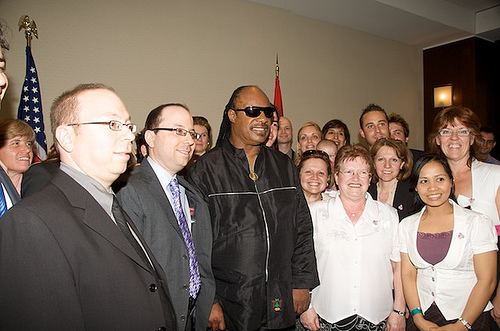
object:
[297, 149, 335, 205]
person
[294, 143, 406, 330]
person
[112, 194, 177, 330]
tie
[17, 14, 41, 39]
eagle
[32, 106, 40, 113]
stars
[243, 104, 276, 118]
glasses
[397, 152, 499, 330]
people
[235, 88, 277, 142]
face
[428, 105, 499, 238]
woman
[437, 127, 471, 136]
glasses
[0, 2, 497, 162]
room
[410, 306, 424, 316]
bracelet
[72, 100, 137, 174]
man's face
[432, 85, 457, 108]
light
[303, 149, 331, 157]
sunglasses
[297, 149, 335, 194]
head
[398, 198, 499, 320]
shirt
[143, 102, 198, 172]
head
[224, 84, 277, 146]
head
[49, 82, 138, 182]
head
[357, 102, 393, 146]
head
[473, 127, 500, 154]
head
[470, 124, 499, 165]
man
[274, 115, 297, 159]
man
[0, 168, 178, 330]
suit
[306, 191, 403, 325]
blouse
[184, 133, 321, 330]
shirt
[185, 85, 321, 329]
black man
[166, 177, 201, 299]
neck tie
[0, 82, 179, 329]
guy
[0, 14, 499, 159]
wall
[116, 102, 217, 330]
man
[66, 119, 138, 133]
glasses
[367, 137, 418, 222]
woman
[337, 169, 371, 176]
glasses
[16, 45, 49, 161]
flag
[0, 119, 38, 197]
woman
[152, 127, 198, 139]
glasses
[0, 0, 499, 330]
camera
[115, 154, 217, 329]
suit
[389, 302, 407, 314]
wrist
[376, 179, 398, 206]
shirt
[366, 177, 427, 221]
blazer